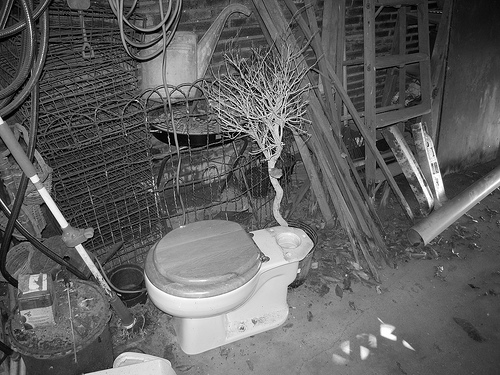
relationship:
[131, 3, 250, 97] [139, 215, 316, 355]
can above toilet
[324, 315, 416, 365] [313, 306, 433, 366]
sunlight on floor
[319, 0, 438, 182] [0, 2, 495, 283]
ladder against wall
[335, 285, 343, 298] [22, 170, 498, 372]
leaf on ground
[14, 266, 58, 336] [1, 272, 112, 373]
box on bucket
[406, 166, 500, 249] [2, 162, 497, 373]
pipe sitting on floor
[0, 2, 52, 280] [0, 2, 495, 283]
hose hanging on wall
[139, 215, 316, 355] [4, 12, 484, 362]
toilet abandoned alley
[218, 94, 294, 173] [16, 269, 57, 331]
grass on box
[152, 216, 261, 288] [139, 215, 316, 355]
lid on toilet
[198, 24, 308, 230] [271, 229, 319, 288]
leafless tree in pot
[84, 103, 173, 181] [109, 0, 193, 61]
loops of cord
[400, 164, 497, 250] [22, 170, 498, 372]
pipe on ground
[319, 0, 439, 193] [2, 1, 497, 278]
ladder leaning brick wall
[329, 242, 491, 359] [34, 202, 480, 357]
leaves scattered floor